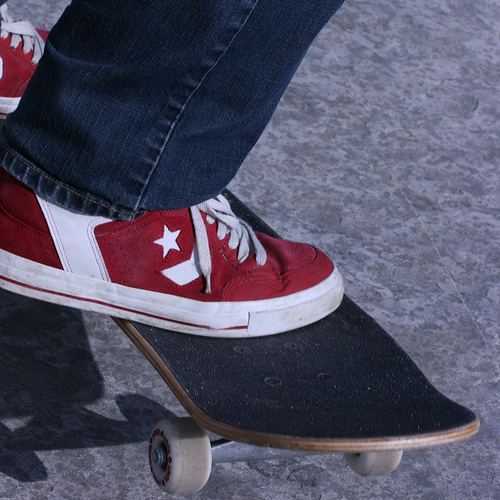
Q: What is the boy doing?
A: Skateboarding.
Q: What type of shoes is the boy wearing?
A: Red skateboarding shoes.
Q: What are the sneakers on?
A: Skateboard.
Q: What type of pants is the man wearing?
A: Blue jeans.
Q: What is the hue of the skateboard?
A: Black.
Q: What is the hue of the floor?
A: Gray.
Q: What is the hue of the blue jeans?
A: Dark blue.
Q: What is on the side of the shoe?
A: White Star.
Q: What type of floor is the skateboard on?
A: Gray concrete.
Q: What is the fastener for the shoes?
A: Laces.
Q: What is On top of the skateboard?
A: A red shoe.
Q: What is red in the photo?
A: The shoe.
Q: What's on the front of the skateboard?
A: Two front wheels.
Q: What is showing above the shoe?
A: A pant leg.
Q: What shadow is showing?
A: The shadow of the skateboard.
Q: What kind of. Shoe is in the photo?
A: Converse.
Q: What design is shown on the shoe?
A: A star.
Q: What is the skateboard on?
A: A road.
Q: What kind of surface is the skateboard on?
A: Granite.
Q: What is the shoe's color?
A: Red.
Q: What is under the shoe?
A: Skateboard.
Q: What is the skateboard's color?
A: Black.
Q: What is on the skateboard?
A: A person.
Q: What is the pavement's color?
A: Gray.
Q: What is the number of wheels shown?
A: 2.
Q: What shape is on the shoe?
A: Star.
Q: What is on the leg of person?
A: Jeans.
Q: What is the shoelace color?
A: White.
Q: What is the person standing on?
A: Skateboard.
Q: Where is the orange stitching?
A: On seam.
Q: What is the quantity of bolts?
A: Four.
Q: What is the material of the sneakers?
A: Red suede.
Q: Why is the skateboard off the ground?
A: Doing a jump.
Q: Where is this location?
A: Skate park.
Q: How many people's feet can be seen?
A: One.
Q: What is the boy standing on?
A: Skateboard.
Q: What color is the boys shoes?
A: Red.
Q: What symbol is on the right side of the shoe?
A: Star.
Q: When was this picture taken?
A: Daytime.